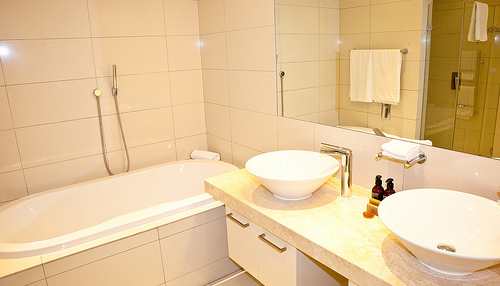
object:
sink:
[244, 149, 342, 202]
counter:
[204, 167, 499, 285]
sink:
[377, 188, 500, 276]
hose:
[93, 64, 131, 174]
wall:
[1, 1, 202, 185]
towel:
[349, 48, 402, 105]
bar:
[348, 48, 409, 54]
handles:
[256, 232, 287, 253]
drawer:
[225, 213, 250, 229]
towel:
[467, 1, 489, 44]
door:
[423, 1, 500, 156]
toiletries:
[371, 174, 384, 201]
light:
[0, 42, 15, 61]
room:
[1, 1, 498, 284]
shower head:
[111, 64, 118, 96]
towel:
[190, 149, 221, 161]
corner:
[164, 2, 231, 166]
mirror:
[272, 0, 498, 159]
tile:
[89, 35, 168, 78]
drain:
[437, 243, 456, 253]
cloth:
[459, 50, 480, 71]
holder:
[461, 50, 478, 53]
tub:
[0, 158, 244, 284]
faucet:
[321, 142, 353, 198]